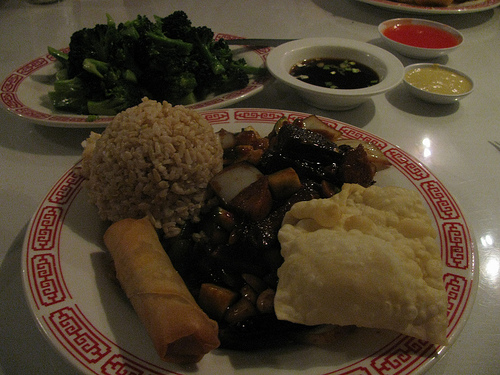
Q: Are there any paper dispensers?
A: No, there are no paper dispensers.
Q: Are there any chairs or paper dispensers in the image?
A: No, there are no paper dispensers or chairs.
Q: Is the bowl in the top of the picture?
A: Yes, the bowl is in the top of the image.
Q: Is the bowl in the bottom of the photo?
A: No, the bowl is in the top of the image.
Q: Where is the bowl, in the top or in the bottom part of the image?
A: The bowl is in the top of the image.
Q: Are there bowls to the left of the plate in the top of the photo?
A: No, the bowl is to the right of the plate.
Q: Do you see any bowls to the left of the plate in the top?
A: No, the bowl is to the right of the plate.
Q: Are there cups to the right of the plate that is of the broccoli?
A: No, there is a bowl to the right of the plate.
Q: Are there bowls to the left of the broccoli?
A: No, the bowl is to the right of the broccoli.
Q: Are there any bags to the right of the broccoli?
A: No, there is a bowl to the right of the broccoli.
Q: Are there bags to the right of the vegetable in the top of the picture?
A: No, there is a bowl to the right of the broccoli.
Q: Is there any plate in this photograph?
A: Yes, there is a plate.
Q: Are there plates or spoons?
A: Yes, there is a plate.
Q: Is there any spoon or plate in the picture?
A: Yes, there is a plate.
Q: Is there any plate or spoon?
A: Yes, there is a plate.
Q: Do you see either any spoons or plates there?
A: Yes, there is a plate.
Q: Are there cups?
A: No, there are no cups.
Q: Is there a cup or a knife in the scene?
A: No, there are no cups or knives.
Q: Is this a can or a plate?
A: This is a plate.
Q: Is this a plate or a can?
A: This is a plate.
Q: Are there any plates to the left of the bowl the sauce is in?
A: Yes, there is a plate to the left of the bowl.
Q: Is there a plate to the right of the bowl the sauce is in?
A: No, the plate is to the left of the bowl.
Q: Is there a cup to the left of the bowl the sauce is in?
A: No, there is a plate to the left of the bowl.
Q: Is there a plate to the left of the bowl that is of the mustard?
A: Yes, there is a plate to the left of the bowl.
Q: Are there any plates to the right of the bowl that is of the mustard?
A: No, the plate is to the left of the bowl.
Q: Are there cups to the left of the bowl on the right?
A: No, there is a plate to the left of the bowl.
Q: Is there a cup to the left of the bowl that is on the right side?
A: No, there is a plate to the left of the bowl.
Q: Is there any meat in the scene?
A: Yes, there is meat.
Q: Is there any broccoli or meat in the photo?
A: Yes, there is meat.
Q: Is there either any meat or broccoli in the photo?
A: Yes, there is meat.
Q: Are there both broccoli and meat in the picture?
A: Yes, there are both meat and broccoli.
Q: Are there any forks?
A: No, there are no forks.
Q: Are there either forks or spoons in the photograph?
A: No, there are no forks or spoons.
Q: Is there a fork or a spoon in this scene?
A: No, there are no forks or spoons.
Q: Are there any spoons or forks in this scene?
A: No, there are no forks or spoons.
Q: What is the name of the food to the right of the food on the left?
A: The food is meat.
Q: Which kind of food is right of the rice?
A: The food is meat.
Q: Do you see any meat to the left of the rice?
A: No, the meat is to the right of the rice.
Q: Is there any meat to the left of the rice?
A: No, the meat is to the right of the rice.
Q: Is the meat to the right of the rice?
A: Yes, the meat is to the right of the rice.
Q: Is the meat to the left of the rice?
A: No, the meat is to the right of the rice.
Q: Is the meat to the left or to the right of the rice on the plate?
A: The meat is to the right of the rice.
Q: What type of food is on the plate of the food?
A: The food is meat.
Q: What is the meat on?
A: The meat is on the plate.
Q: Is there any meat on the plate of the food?
A: Yes, there is meat on the plate.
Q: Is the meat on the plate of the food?
A: Yes, the meat is on the plate.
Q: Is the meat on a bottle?
A: No, the meat is on the plate.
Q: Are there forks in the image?
A: No, there are no forks.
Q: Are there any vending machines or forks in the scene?
A: No, there are no forks or vending machines.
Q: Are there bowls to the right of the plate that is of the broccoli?
A: Yes, there is a bowl to the right of the plate.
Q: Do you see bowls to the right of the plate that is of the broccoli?
A: Yes, there is a bowl to the right of the plate.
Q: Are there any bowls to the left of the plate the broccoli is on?
A: No, the bowl is to the right of the plate.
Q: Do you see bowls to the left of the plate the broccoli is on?
A: No, the bowl is to the right of the plate.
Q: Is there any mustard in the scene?
A: Yes, there is mustard.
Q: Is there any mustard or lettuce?
A: Yes, there is mustard.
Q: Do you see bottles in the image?
A: No, there are no bottles.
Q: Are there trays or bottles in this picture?
A: No, there are no bottles or trays.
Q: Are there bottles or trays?
A: No, there are no bottles or trays.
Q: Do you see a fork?
A: No, there are no forks.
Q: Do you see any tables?
A: Yes, there is a table.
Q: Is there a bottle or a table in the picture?
A: Yes, there is a table.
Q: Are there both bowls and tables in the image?
A: Yes, there are both a table and a bowl.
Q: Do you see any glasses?
A: No, there are no glasses.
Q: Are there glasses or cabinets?
A: No, there are no glasses or cabinets.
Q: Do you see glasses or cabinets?
A: No, there are no glasses or cabinets.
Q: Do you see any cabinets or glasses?
A: No, there are no glasses or cabinets.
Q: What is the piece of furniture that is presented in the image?
A: The piece of furniture is a table.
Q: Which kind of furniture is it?
A: The piece of furniture is a table.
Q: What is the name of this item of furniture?
A: That is a table.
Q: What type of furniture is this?
A: That is a table.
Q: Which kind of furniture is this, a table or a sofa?
A: That is a table.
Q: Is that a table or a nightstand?
A: That is a table.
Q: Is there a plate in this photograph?
A: Yes, there is a plate.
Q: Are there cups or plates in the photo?
A: Yes, there is a plate.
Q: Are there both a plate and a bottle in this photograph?
A: No, there is a plate but no bottles.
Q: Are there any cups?
A: No, there are no cups.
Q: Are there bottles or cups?
A: No, there are no cups or bottles.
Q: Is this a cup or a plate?
A: This is a plate.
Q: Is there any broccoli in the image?
A: Yes, there is broccoli.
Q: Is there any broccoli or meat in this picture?
A: Yes, there is broccoli.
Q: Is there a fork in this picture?
A: No, there are no forks.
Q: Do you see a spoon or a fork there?
A: No, there are no forks or spoons.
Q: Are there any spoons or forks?
A: No, there are no forks or spoons.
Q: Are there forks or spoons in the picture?
A: No, there are no forks or spoons.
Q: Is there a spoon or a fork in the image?
A: No, there are no forks or spoons.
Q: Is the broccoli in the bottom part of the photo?
A: No, the broccoli is in the top of the image.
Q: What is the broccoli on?
A: The broccoli is on the plate.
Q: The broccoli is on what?
A: The broccoli is on the plate.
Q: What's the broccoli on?
A: The broccoli is on the plate.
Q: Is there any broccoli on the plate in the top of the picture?
A: Yes, there is broccoli on the plate.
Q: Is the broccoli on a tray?
A: No, the broccoli is on the plate.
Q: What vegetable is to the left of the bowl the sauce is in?
A: The vegetable is broccoli.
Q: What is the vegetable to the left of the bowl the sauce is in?
A: The vegetable is broccoli.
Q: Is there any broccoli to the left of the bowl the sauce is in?
A: Yes, there is broccoli to the left of the bowl.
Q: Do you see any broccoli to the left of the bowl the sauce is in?
A: Yes, there is broccoli to the left of the bowl.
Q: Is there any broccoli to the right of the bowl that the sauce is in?
A: No, the broccoli is to the left of the bowl.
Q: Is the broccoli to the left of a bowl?
A: Yes, the broccoli is to the left of a bowl.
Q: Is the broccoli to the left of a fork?
A: No, the broccoli is to the left of a bowl.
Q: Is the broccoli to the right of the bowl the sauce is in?
A: No, the broccoli is to the left of the bowl.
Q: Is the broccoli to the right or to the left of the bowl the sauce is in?
A: The broccoli is to the left of the bowl.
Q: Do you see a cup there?
A: No, there are no cups.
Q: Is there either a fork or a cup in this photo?
A: No, there are no cups or forks.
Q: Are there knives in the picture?
A: No, there are no knives.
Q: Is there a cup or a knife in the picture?
A: No, there are no knives or cups.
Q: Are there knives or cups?
A: No, there are no knives or cups.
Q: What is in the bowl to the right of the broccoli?
A: The sauce is in the bowl.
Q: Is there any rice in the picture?
A: Yes, there is rice.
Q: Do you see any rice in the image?
A: Yes, there is rice.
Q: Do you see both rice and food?
A: Yes, there are both rice and food.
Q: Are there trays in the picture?
A: No, there are no trays.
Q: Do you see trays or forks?
A: No, there are no trays or forks.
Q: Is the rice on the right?
A: No, the rice is on the left of the image.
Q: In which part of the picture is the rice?
A: The rice is on the left of the image.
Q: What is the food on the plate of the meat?
A: The food is rice.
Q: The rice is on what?
A: The rice is on the plate.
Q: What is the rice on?
A: The rice is on the plate.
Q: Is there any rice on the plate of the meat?
A: Yes, there is rice on the plate.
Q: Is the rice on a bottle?
A: No, the rice is on the plate.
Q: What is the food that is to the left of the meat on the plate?
A: The food is rice.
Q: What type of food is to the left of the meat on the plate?
A: The food is rice.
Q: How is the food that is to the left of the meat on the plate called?
A: The food is rice.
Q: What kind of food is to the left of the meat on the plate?
A: The food is rice.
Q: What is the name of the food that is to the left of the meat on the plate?
A: The food is rice.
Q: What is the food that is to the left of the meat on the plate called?
A: The food is rice.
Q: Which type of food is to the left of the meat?
A: The food is rice.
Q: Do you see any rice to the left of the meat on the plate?
A: Yes, there is rice to the left of the meat.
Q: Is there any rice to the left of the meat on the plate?
A: Yes, there is rice to the left of the meat.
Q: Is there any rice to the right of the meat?
A: No, the rice is to the left of the meat.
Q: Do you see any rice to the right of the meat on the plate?
A: No, the rice is to the left of the meat.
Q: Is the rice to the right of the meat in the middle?
A: No, the rice is to the left of the meat.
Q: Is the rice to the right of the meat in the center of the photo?
A: No, the rice is to the left of the meat.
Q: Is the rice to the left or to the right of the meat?
A: The rice is to the left of the meat.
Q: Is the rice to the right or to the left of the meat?
A: The rice is to the left of the meat.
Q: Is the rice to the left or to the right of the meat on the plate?
A: The rice is to the left of the meat.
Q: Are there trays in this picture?
A: No, there are no trays.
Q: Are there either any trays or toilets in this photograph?
A: No, there are no trays or toilets.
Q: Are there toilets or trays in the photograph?
A: No, there are no trays or toilets.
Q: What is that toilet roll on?
A: The toilet roll is on the plate.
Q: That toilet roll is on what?
A: The toilet roll is on the plate.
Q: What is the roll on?
A: The toilet roll is on the plate.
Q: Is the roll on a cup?
A: No, the roll is on the plate.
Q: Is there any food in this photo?
A: Yes, there is food.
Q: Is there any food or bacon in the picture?
A: Yes, there is food.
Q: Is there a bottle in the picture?
A: No, there are no bottles.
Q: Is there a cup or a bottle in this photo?
A: No, there are no bottles or cups.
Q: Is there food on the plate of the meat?
A: Yes, there is food on the plate.